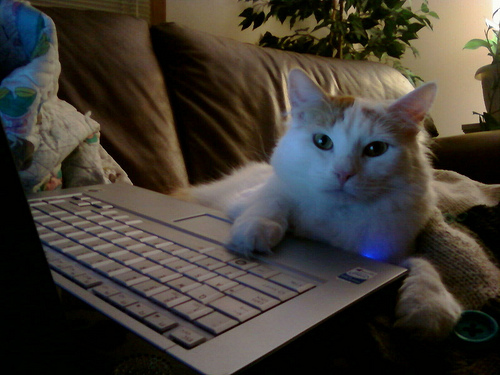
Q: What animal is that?
A: A cat.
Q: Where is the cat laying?
A: On the couch.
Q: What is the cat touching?
A: A laptop.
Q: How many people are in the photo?
A: None.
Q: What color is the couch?
A: Brown.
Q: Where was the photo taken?
A: In the living room.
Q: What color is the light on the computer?
A: Blue.